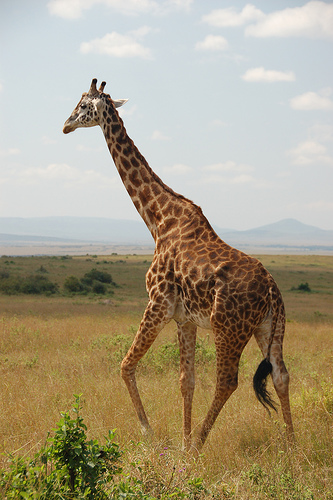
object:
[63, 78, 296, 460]
giraffe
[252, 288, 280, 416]
tail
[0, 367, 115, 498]
plant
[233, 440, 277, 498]
grass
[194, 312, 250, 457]
leg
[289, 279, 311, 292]
bush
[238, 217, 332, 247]
mountain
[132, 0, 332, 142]
sky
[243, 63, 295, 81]
cloud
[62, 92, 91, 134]
face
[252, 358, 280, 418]
hair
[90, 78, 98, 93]
horn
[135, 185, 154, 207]
spot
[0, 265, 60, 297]
bushes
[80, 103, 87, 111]
eye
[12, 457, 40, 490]
flower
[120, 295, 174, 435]
leg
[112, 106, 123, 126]
hair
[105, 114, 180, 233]
neck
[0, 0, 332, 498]
field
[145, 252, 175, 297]
shoulder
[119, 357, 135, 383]
knee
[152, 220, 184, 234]
wrinkles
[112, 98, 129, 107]
ear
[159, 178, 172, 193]
mane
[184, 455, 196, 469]
hoove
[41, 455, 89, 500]
wildflowers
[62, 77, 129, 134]
head